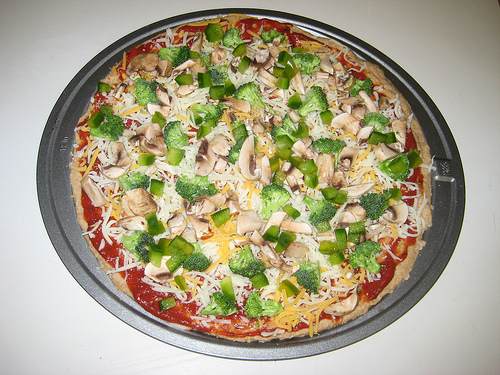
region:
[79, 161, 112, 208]
A PEACE OF MUSHROOM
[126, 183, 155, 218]
A PEACE OF MUSHROOM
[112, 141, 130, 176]
A PEACE OF MUSHROOM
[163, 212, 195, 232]
A PEACE OF MUSHROOM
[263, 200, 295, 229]
A PEACE OF MUSHROOM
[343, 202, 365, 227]
A PEACE OF MUSHROOM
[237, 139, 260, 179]
A PEACE OF MUSHROOM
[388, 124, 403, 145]
A PEACE OF MUSHROOM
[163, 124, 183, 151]
A PEACE OF VEGATABLE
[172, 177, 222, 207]
A PIECE OF VEGATABLE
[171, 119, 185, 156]
that is green vegatable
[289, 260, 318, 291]
that is green vegatable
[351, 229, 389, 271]
that is green vegatable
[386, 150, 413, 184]
that is green vegatable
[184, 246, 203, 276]
that is green vegatable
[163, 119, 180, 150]
that is green vegatable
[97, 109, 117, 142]
that is green vegatable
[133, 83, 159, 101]
that is green vegatable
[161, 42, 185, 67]
that is green vegatable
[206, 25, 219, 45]
that is green vegatable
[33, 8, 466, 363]
Silver pan under a pizza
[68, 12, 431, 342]
Veggie pizza with cheese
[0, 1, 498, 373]
White table top underneath pizza pan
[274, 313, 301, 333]
Pieces of shredded cheddar cheese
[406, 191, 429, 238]
Pieces of shredded mozzarella cheese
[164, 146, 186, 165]
Diced green bell pepper cube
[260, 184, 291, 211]
Small raw broccoli floret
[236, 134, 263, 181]
Slice of raw mushroom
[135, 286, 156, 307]
Red marinara pizza sauce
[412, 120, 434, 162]
Section of thin crust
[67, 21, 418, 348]
pizza is on platter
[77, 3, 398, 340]
pizza is not cooked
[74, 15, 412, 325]
red sauce on pizza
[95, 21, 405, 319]
white and yellow cheese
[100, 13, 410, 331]
green vegetables on pizza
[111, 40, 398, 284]
broccoli on pizza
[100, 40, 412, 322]
grey platter on white table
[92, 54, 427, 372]
tan mushrooms on pizza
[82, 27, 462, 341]
pizza on metal tray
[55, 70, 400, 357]
sauce covers edges of pizza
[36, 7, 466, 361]
the metal pizza pan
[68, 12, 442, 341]
the uncooked pizza on the pan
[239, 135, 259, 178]
the slice mushroom on the pizza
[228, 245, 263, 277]
the piece of broccoli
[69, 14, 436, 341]
the tomato sauce on the pizza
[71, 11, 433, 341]
the shredded cheese on the pizza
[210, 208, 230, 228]
the piece of green bell pepper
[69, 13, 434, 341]
the toppings on the pizza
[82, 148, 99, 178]
the piece of yellow shredded cheese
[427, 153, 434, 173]
the piece of white shredded cheese